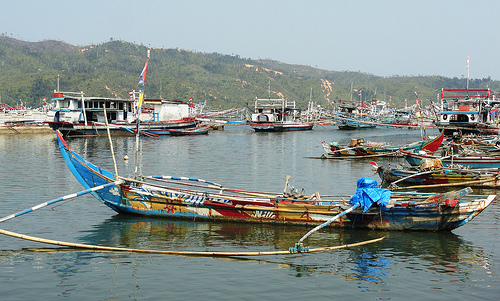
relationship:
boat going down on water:
[55, 128, 493, 259] [0, 0, 498, 298]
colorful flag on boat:
[129, 37, 163, 184] [49, 44, 209, 136]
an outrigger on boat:
[338, 168, 420, 234] [55, 125, 498, 229]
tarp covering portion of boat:
[347, 177, 388, 208] [55, 125, 498, 229]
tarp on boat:
[341, 177, 391, 209] [55, 125, 498, 229]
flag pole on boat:
[128, 48, 153, 190] [55, 125, 498, 229]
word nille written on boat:
[250, 208, 277, 221] [55, 125, 498, 229]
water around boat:
[1, 108, 493, 296] [51, 137, 406, 249]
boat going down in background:
[55, 128, 493, 259] [56, 82, 360, 139]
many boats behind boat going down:
[19, 63, 499, 268] [55, 128, 493, 259]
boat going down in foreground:
[55, 128, 493, 259] [38, 139, 424, 224]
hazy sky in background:
[145, 96, 207, 145] [97, 5, 418, 53]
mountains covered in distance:
[0, 35, 498, 112] [143, 38, 415, 156]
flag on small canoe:
[113, 71, 162, 104] [115, 122, 220, 141]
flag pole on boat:
[129, 37, 160, 192] [70, 118, 470, 218]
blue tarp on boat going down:
[340, 170, 403, 224] [55, 128, 493, 259]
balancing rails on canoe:
[0, 173, 402, 275] [26, 143, 406, 267]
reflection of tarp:
[67, 203, 167, 282] [335, 167, 392, 223]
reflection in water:
[67, 203, 167, 282] [273, 234, 432, 273]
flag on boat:
[126, 49, 150, 104] [40, 87, 215, 120]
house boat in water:
[83, 67, 220, 155] [99, 154, 267, 175]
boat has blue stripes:
[50, 131, 401, 269] [65, 153, 267, 249]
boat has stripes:
[48, 126, 497, 296] [120, 164, 215, 198]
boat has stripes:
[123, 119, 228, 149] [125, 159, 247, 213]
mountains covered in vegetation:
[29, 30, 330, 104] [168, 47, 201, 73]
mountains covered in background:
[29, 30, 330, 104] [108, 59, 443, 113]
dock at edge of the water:
[12, 105, 52, 136] [2, 120, 105, 197]